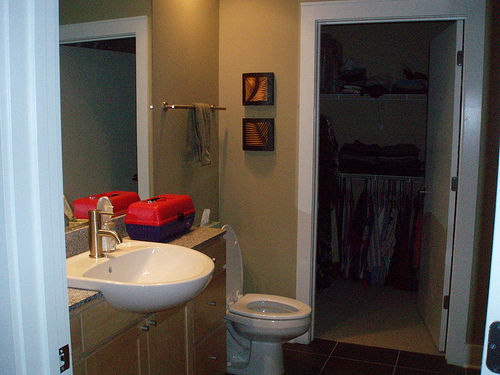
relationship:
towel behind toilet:
[182, 102, 213, 168] [225, 222, 312, 370]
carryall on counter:
[122, 192, 196, 244] [281, 30, 461, 358]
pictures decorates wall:
[241, 72, 275, 104] [216, 1, 297, 340]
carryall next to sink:
[120, 196, 195, 243] [68, 222, 196, 302]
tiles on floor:
[253, 326, 491, 373] [243, 317, 488, 372]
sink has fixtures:
[72, 244, 217, 305] [88, 208, 122, 256]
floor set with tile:
[285, 335, 480, 373] [328, 341, 399, 366]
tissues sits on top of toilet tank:
[193, 205, 222, 230] [206, 219, 314, 373]